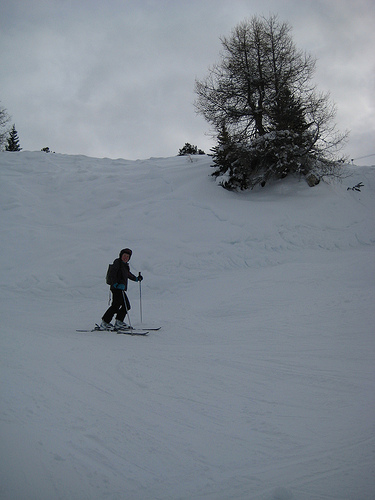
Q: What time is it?
A: Afternoon.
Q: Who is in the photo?
A: A person.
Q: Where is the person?
A: In the snow.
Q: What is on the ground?
A: Snow.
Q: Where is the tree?
A: Behind the person.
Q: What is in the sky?
A: Clouds.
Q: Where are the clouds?
A: In the sky.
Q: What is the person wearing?
A: Skis.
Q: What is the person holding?
A: Ski poles.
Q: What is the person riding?
A: Some skis.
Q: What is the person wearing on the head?
A: A hat.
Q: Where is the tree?
A: At the top of the hill.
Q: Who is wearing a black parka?
A: The boy.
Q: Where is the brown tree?
A: At the top of the hill.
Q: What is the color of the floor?
A: White.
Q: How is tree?
A: Without leaves.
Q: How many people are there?
A: One.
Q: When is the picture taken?
A: Daytime.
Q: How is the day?
A: Cloudy.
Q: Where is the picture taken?
A: Out on the ski slopes.